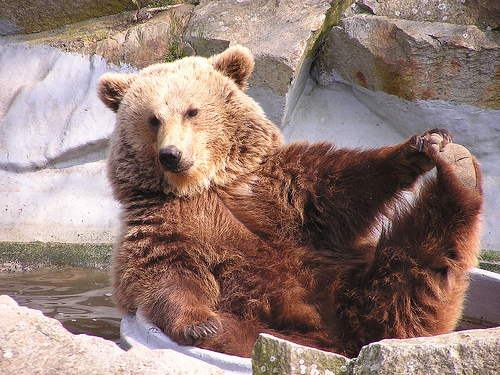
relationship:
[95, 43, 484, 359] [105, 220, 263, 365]
animal resting on back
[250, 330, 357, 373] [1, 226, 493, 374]
rock beside pool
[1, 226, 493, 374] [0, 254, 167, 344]
pool has water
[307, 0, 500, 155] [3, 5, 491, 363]
rock in enclave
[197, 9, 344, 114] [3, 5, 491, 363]
rocks in enclave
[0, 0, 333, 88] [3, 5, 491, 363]
rocks in enclave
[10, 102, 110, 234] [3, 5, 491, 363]
rocks in enclave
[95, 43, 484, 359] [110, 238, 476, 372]
animal reclining in tub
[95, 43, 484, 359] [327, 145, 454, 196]
animal touching left paw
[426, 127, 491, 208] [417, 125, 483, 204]
foot with claws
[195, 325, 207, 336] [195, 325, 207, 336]
claw on claw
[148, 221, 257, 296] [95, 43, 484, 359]
fur on animal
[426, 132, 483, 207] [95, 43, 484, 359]
foot on animal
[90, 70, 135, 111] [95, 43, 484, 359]
ear on animal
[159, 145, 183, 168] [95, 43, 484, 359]
black nose of animal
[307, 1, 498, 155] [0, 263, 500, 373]
rock above water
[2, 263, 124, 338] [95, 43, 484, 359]
water behind animal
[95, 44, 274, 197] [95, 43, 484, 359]
head of a animal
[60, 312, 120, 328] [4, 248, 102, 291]
ripples in water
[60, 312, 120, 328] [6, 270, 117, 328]
ripples in water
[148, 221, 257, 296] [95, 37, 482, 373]
fur on animal